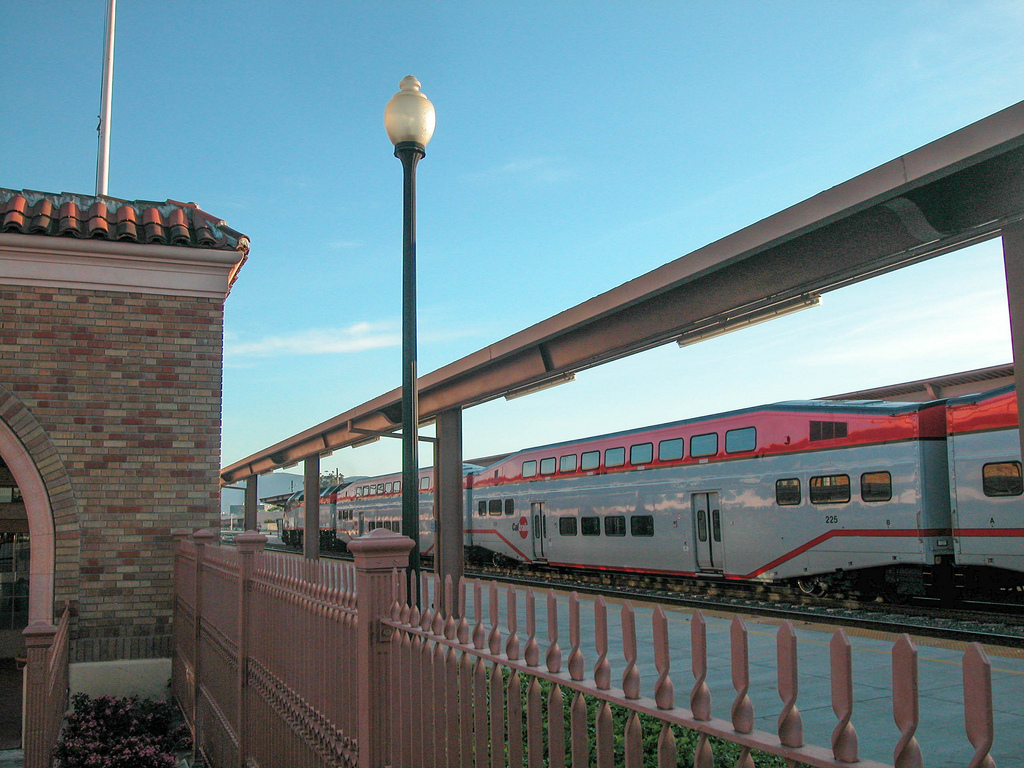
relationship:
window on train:
[978, 462, 1017, 499] [284, 400, 1022, 606]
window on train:
[857, 460, 893, 502] [284, 400, 1022, 606]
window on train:
[806, 474, 848, 500] [284, 400, 1022, 606]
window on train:
[579, 510, 596, 536] [284, 400, 1022, 606]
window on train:
[484, 498, 503, 512] [284, 400, 1022, 606]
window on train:
[500, 496, 517, 516] [284, 400, 1022, 606]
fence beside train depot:
[178, 518, 1024, 763] [87, 337, 619, 733]